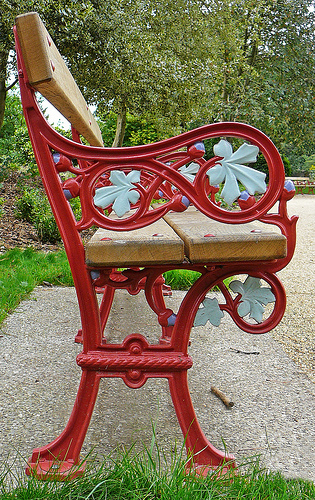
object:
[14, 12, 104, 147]
back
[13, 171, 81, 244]
bush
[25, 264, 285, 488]
legs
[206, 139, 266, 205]
design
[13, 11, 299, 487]
bench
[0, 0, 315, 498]
park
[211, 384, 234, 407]
twigs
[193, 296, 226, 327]
leaf design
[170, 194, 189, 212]
flower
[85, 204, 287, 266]
bolts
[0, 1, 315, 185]
trees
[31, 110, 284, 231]
ornate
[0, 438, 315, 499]
grass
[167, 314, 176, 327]
tip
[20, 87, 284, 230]
arms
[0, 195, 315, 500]
ground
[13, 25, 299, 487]
metal work